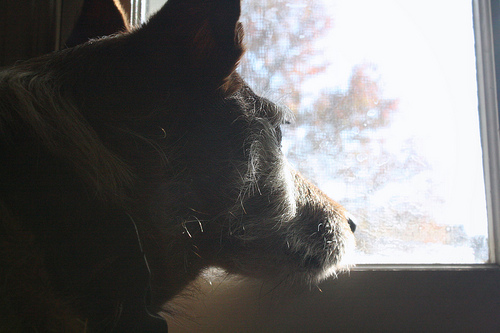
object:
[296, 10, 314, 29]
leaf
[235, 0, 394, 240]
tree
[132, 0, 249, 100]
ear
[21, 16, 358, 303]
dog fur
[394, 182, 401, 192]
?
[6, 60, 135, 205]
white hair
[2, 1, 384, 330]
dog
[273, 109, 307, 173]
eyes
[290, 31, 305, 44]
leaf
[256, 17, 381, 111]
stem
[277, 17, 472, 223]
window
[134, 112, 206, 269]
black collar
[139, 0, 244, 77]
ears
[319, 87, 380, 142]
leaf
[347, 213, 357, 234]
nose